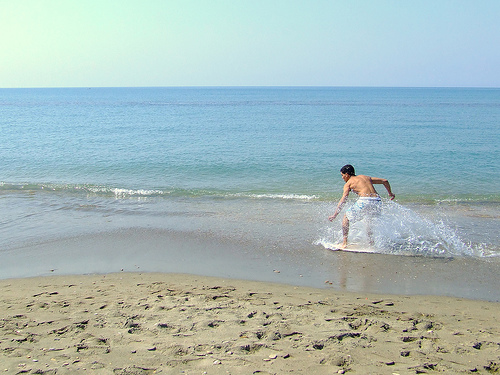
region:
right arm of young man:
[371, 175, 392, 192]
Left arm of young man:
[333, 175, 351, 210]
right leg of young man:
[360, 215, 376, 247]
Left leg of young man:
[337, 203, 352, 246]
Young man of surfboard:
[326, 157, 399, 257]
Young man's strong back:
[346, 175, 374, 200]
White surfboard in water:
[318, 241, 408, 256]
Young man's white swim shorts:
[343, 190, 383, 218]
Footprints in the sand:
[38, 280, 463, 366]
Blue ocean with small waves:
[10, 123, 330, 220]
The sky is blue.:
[50, 14, 459, 81]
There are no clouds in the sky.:
[2, 1, 497, 76]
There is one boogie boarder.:
[310, 135, 462, 305]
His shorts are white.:
[341, 190, 388, 229]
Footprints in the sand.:
[40, 272, 407, 357]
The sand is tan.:
[27, 287, 362, 351]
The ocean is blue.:
[65, 107, 447, 148]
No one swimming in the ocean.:
[3, 85, 485, 128]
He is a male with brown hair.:
[317, 154, 402, 200]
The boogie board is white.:
[309, 227, 412, 262]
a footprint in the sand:
[10, 342, 35, 357]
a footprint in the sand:
[242, 340, 265, 357]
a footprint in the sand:
[280, 350, 300, 366]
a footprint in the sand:
[338, 325, 372, 349]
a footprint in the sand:
[400, 322, 422, 349]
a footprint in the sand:
[411, 355, 451, 373]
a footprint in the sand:
[474, 333, 496, 365]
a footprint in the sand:
[208, 290, 234, 306]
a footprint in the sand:
[208, 279, 234, 299]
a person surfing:
[308, 144, 453, 271]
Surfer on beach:
[320, 156, 404, 261]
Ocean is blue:
[0, 86, 497, 188]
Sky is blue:
[1, 2, 496, 87]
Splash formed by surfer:
[307, 187, 491, 264]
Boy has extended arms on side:
[306, 156, 408, 258]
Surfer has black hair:
[320, 155, 400, 255]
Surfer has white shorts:
[318, 158, 400, 255]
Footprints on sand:
[0, 282, 498, 372]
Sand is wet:
[10, 205, 495, 280]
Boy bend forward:
[317, 157, 404, 257]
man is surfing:
[288, 115, 450, 319]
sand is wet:
[13, 253, 338, 373]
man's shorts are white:
[303, 151, 442, 300]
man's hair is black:
[315, 147, 396, 210]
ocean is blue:
[37, 71, 452, 163]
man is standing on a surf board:
[292, 155, 452, 296]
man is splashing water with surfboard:
[296, 148, 478, 304]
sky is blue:
[74, 3, 490, 185]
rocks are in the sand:
[138, 322, 360, 369]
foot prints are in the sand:
[29, 291, 404, 370]